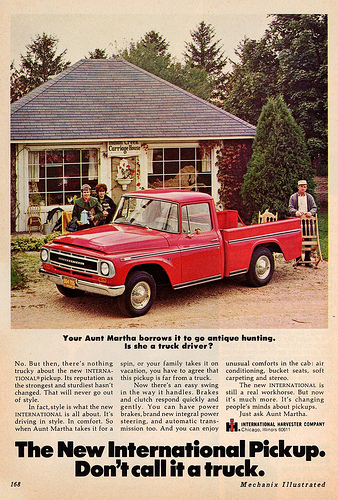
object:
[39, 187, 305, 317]
pickup truck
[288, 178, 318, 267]
man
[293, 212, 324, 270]
chair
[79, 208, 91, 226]
antiques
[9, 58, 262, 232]
antique store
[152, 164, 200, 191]
carousel horse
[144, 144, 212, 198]
window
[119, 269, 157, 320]
tire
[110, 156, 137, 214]
door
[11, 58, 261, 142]
roof of house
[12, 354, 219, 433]
two paragraphs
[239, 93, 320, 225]
christmas tree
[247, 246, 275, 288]
back wheel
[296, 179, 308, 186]
hat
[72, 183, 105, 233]
lady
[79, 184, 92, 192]
gray hair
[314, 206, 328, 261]
grass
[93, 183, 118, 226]
woman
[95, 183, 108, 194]
red hair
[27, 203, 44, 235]
chair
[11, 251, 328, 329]
gravel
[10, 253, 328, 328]
dirt road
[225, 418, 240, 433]
logo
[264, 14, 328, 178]
pine trees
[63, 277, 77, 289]
license plate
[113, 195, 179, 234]
windshield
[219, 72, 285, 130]
tree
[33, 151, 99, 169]
flowering plant